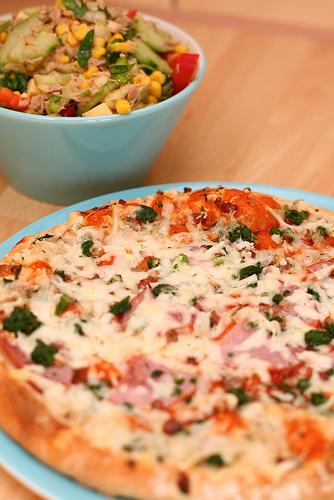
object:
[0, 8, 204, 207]
bowl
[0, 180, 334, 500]
plate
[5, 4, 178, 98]
meat and veggies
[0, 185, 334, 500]
pizza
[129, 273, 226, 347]
cheese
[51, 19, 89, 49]
corn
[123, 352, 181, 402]
ham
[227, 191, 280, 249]
sauce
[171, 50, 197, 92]
red pepper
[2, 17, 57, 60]
cucumber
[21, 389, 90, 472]
crust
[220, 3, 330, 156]
table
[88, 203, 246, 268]
portion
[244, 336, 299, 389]
bacon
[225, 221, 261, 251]
spinach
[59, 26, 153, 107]
vegetable salad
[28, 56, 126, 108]
salad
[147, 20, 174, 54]
carrot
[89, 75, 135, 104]
onion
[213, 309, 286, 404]
chunks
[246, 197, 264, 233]
tomato sauce